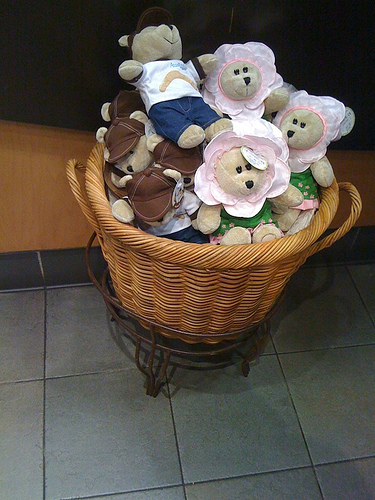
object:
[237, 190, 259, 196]
mouth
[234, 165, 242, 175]
eye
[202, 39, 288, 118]
stuffed bear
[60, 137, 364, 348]
basket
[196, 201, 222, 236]
arm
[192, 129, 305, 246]
teddy bear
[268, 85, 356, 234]
bear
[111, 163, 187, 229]
teddy bear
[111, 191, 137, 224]
leg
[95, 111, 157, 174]
teddy bear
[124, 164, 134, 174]
nose